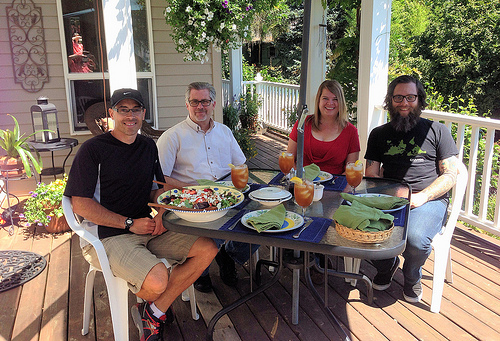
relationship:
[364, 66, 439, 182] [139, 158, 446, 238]
man at table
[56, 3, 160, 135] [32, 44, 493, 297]
window behind people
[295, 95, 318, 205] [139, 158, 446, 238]
pole through table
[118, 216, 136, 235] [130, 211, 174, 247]
watch on hand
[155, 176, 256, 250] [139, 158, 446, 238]
bowl on table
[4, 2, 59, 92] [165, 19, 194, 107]
artwork on wall